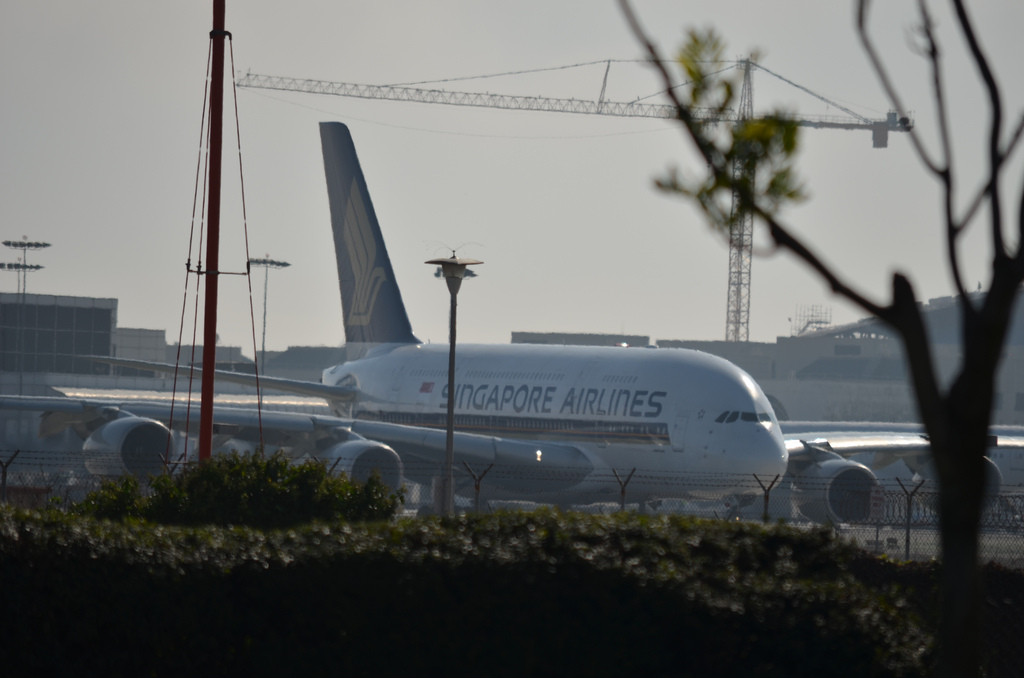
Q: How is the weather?
A: Foggy.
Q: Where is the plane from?
A: Earth.